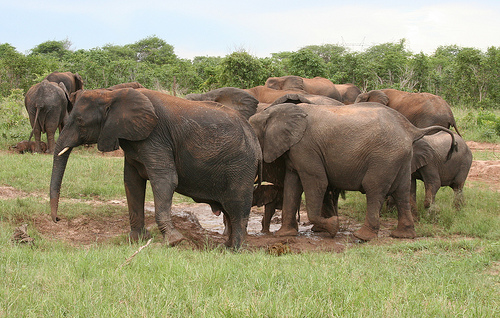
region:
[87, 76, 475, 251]
the elephants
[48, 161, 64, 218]
the elephants trunk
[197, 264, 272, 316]
the tall green grass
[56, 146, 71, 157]
the elephants tusk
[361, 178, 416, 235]
the elephants back legs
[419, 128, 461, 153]
the elephants tail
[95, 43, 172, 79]
the green trees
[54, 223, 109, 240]
the brown dirt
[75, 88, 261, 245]
the elephant is standing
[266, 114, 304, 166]
the elephants ear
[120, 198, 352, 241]
Water hole in grassy field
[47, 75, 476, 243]
Herd of elephants gathered around water hole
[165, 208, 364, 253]
Muddy ground near water hole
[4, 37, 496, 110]
Leaf covered trees in background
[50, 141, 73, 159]
Tusk of an elephant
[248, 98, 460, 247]
Elephant with one foot in the air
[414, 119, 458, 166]
Extended tail of elephant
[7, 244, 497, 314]
Grass covered field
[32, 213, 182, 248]
Bare patch of ground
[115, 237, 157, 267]
Stick on ground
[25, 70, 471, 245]
Elephants in a herd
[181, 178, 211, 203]
The stomach of the elephant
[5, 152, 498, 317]
Grass below the elephants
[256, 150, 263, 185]
The tail of the elephant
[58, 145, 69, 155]
The tusk of the elephant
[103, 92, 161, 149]
The left ear of the elephant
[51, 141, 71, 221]
The trunk of the elephant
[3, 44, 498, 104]
Trees behind the elephants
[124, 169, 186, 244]
The front legs of the elephant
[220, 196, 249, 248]
The back legs of the elephant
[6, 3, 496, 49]
the sky is really bright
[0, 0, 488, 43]
the sky is a really light green color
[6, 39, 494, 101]
a whole bunch of trees outside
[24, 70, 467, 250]
elephants are outside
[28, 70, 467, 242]
the elephants are in a group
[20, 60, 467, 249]
the elephants are gray and brown in color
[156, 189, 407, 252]
the mud puddle in the ground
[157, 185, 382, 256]
the mud is light brown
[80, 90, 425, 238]
elephants are standing in the mud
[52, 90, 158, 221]
The face of an elephant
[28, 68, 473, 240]
a herd of elephants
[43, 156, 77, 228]
a elephants trunk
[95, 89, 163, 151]
a gray elephants ear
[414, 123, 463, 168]
a elephants gray tail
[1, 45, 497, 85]
a line of leafy trees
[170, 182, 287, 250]
a brown water hole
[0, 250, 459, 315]
a green grassy area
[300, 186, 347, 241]
a elephants left leg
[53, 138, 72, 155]
a tusk on a elephant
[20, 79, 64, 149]
the back of a elephant